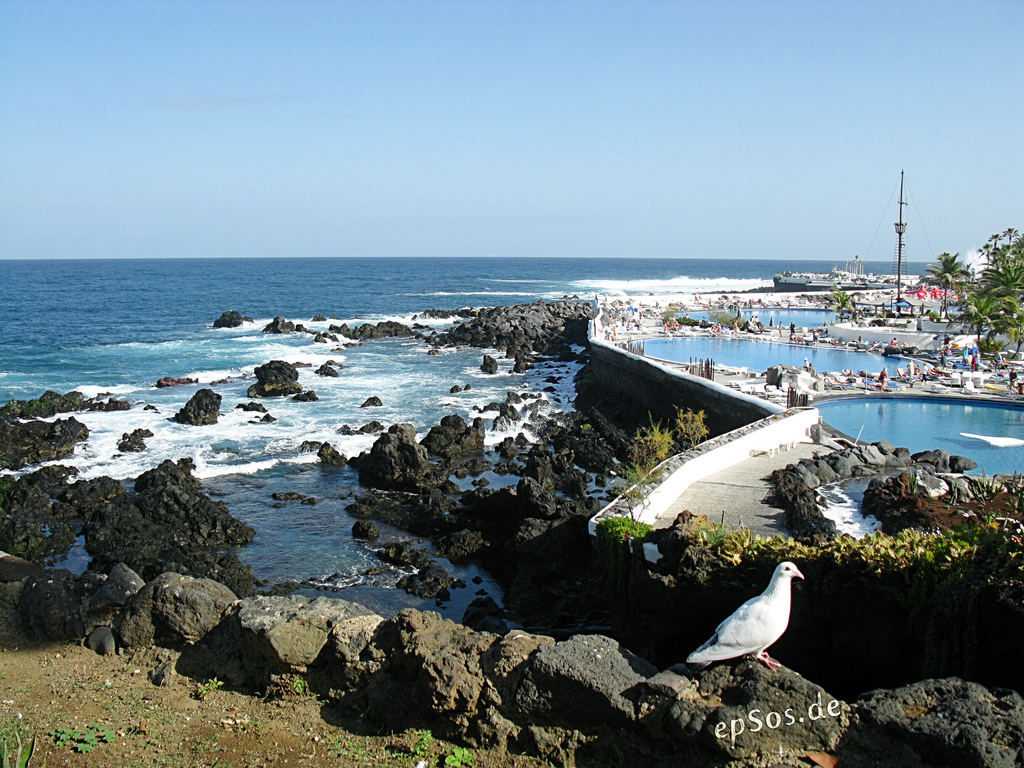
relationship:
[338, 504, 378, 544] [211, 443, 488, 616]
rock in water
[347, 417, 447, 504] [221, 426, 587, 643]
rock in water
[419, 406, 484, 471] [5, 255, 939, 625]
rock in ocean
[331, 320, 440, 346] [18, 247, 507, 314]
rock in ocean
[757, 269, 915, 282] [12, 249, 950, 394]
boat on water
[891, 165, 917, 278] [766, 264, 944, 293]
mast on ship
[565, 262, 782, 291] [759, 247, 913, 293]
wave by boat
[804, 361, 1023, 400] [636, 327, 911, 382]
people by pool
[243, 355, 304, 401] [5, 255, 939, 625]
rock jutting out of ocean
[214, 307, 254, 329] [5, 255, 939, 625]
rock jutting out of ocean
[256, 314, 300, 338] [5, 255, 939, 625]
rock jutting out of ocean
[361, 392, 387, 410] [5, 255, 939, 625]
rock jutting out of ocean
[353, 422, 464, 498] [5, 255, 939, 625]
rock jutting out of ocean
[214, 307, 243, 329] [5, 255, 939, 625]
rock jutting out of ocean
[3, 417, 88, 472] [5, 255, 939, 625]
rock jutting out of ocean